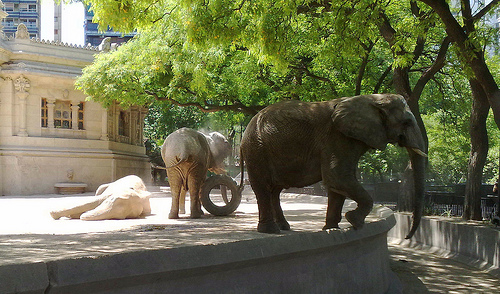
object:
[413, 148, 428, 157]
tusk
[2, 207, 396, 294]
edge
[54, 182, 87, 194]
bench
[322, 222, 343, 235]
foot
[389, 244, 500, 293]
walkway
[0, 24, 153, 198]
building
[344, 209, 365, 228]
foot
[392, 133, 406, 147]
mouth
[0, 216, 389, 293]
platform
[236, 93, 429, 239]
elephant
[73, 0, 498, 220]
trees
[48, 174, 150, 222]
elephant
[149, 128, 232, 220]
elephant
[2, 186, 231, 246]
floor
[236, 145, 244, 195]
elephant tail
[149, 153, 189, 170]
elephant tail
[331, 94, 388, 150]
ear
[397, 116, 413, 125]
eye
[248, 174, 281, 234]
back legs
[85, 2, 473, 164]
leaves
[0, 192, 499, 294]
ground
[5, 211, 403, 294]
ledge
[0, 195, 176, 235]
sunlight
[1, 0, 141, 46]
building